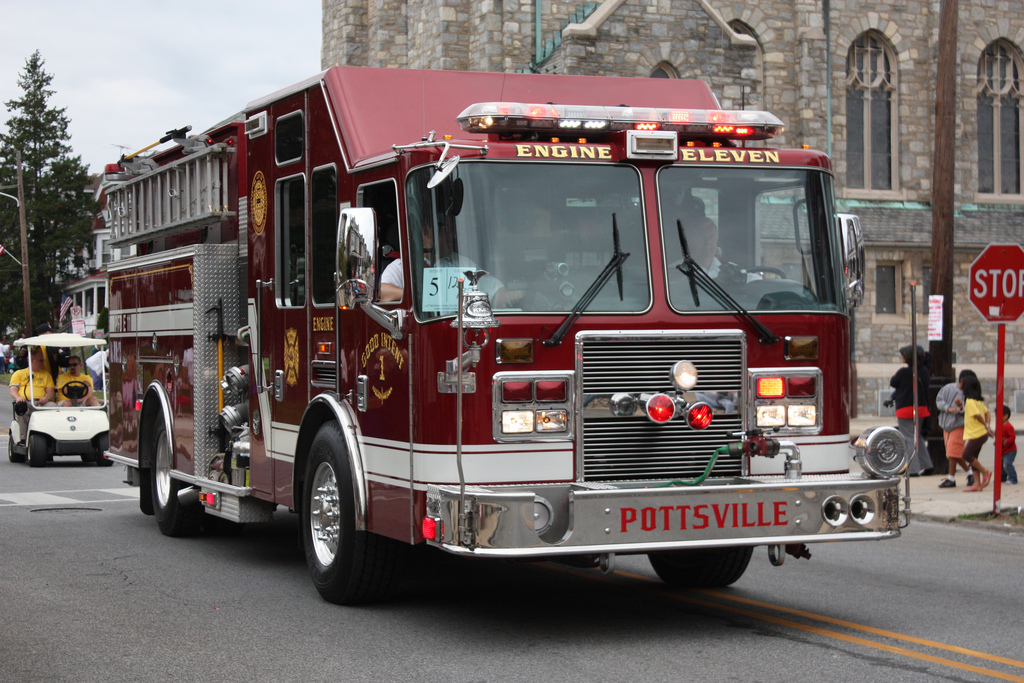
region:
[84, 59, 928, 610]
Fire truck on the street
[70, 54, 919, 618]
Fire truck is on the street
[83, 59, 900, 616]
Red fire truck is on the street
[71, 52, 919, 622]
Fire truck is on the road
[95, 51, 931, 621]
Red fire truck on the road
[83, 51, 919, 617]
Red fire truck is on the road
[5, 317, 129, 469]
Golf cart on the street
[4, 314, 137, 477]
Golf cart is on the street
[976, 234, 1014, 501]
Red and white sign attached to red pole.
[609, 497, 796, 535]
Red letters on front of bumper.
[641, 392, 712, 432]
Red lights on front of truck.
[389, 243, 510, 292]
Person wearing white shirt.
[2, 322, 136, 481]
Golf cart behind fire truck.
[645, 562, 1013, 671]
Yellow lines marking pavement.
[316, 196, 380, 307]
Large mirror on side of truck.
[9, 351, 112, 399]
2 people wearing yellow shirts.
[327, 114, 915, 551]
Front of a Pottsville fire truck.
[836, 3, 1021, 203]
Church windows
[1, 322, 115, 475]
Tennis cart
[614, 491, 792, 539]
Pottsville sign on a fire truck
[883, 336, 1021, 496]
People standing on the sidewalk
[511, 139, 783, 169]
Engine Eleven label on a fire truck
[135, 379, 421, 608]
Fire truck right tires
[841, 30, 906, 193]
a window on a building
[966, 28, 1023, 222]
a window on a building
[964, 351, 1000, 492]
a person walking on a sidewalk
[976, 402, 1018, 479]
a person walking on a sidewalk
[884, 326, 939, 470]
a person walking on a sidewalk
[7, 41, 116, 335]
a tree in a field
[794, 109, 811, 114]
a stone in a wall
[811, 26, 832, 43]
a stone in a wall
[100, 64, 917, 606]
a moving red fire truck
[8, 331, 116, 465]
a white golf cart with two people inside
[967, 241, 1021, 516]
a red stop sign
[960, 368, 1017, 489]
a girl holding her little brothers hand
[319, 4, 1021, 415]
a large stone church building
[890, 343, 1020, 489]
a group of people waiting to cross the street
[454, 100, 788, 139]
light bar on top of fire truck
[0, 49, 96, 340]
a tall green pine tree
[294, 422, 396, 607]
A tire on a vehicle.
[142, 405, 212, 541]
A tire on a vehicle.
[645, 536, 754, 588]
A tire on a vehicle.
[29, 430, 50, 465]
A tire on a vehicle.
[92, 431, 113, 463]
A tire on a vehicle.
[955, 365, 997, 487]
A person walking on a sidewalk.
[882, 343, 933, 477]
A person is standing up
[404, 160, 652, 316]
A window on a vehicle.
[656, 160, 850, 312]
A window on a vehicle.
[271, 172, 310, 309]
A window on a vehicle.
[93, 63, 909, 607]
a red fire engine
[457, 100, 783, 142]
a set of emergency lights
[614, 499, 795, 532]
printed name POTTSVILLE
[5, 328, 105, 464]
a small white golf cart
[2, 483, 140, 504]
a marked pedestrian crosswalk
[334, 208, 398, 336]
a chrome sideview mirror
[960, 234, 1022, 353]
a red stop sign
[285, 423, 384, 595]
front tire of the truck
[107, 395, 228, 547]
back tire of the truck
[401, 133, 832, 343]
front windows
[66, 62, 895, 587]
a large red fire truck